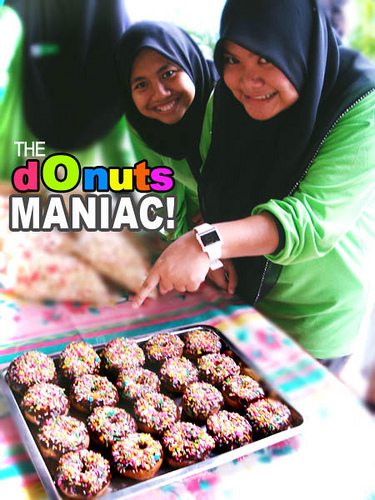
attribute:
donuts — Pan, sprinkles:
[148, 327, 182, 366]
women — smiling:
[65, 31, 217, 138]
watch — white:
[190, 220, 230, 275]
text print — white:
[6, 193, 184, 232]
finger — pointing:
[128, 271, 160, 309]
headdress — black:
[119, 14, 217, 155]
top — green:
[212, 101, 368, 320]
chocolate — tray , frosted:
[89, 325, 257, 447]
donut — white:
[243, 393, 294, 436]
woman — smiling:
[126, 2, 370, 314]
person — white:
[0, 2, 149, 281]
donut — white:
[163, 422, 215, 466]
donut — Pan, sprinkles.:
[132, 391, 180, 431]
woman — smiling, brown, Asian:
[106, 14, 319, 392]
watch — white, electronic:
[194, 222, 225, 272]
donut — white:
[119, 364, 166, 413]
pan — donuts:
[1, 324, 304, 499]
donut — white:
[109, 326, 304, 463]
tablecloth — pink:
[247, 314, 374, 425]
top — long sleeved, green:
[137, 76, 374, 361]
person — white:
[114, 19, 219, 242]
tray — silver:
[0, 323, 302, 496]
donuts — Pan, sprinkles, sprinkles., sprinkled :
[8, 336, 290, 494]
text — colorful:
[7, 146, 178, 197]